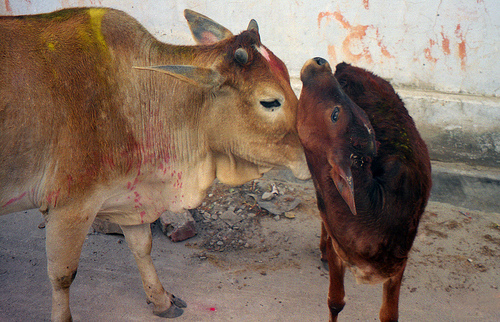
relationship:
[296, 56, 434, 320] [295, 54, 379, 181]
calf has head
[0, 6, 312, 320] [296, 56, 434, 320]
cow sniffing calf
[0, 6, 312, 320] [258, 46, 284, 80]
cow has stain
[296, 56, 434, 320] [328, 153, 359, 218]
calf has ear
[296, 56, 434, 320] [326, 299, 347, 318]
calf has hoof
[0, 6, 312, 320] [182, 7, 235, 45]
cow has ear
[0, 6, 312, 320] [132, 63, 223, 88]
cow has ear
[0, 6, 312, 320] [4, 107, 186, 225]
cow has stains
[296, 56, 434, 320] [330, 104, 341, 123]
calf has eye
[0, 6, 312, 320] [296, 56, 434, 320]
cow kissing calf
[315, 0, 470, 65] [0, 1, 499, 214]
graffiti on wall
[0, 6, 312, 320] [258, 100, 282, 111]
cow has eye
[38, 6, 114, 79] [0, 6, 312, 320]
paint on cow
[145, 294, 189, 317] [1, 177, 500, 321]
hoof on ground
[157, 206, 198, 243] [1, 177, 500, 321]
brick on ground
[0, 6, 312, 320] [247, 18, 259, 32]
cow has horn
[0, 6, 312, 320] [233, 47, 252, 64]
cow has horn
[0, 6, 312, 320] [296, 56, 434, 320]
cow nuzzling calf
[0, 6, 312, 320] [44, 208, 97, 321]
cow has leg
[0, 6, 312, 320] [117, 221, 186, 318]
cow has leg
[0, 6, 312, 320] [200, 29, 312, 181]
cow has head